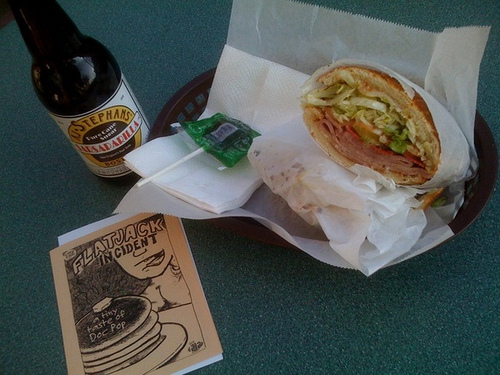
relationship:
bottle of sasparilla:
[10, 1, 152, 186] [10, 0, 150, 185]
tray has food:
[148, 69, 498, 248] [299, 63, 442, 181]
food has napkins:
[299, 63, 442, 181] [124, 122, 273, 214]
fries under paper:
[256, 135, 359, 220] [249, 134, 426, 252]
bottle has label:
[10, 1, 152, 186] [49, 71, 149, 181]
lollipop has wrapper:
[135, 111, 262, 190] [173, 114, 259, 171]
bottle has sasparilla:
[10, 1, 152, 186] [10, 0, 150, 185]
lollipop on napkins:
[135, 111, 262, 190] [124, 122, 273, 214]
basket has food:
[142, 64, 499, 249] [299, 63, 442, 181]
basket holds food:
[142, 64, 499, 249] [299, 63, 442, 181]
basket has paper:
[142, 64, 499, 249] [249, 134, 426, 252]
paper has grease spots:
[249, 134, 426, 252] [269, 159, 326, 209]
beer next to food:
[10, 1, 152, 186] [299, 63, 442, 181]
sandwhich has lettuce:
[302, 61, 441, 186] [316, 80, 417, 152]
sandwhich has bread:
[302, 61, 441, 186] [301, 66, 441, 185]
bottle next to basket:
[10, 1, 152, 186] [142, 64, 499, 249]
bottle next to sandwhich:
[10, 1, 152, 186] [302, 61, 441, 186]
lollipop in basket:
[135, 111, 262, 190] [142, 64, 499, 249]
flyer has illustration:
[49, 213, 223, 373] [62, 216, 207, 374]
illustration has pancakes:
[62, 216, 207, 374] [77, 293, 167, 373]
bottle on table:
[10, 1, 152, 186] [2, 4, 499, 374]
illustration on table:
[62, 216, 207, 374] [2, 4, 499, 374]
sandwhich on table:
[302, 61, 441, 186] [2, 4, 499, 374]